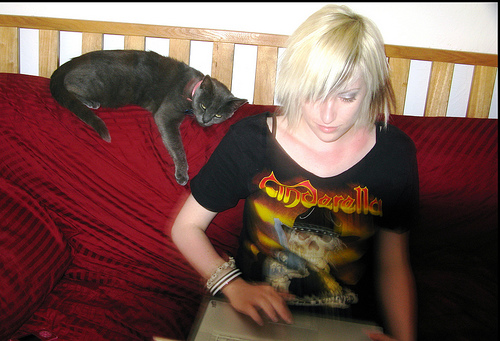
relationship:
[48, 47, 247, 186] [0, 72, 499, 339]
cat lazing on couch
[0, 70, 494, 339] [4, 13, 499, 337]
cushion on sofa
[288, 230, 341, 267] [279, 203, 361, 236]
skeleton wearing cowboy hat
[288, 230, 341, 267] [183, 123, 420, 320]
skeleton on shirt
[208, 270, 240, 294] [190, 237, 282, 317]
bracelet on wrist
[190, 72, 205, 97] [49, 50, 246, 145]
pink collar on cat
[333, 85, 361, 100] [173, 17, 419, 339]
eye shadow on girl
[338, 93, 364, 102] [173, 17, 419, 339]
mascara on girl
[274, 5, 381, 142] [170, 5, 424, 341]
head of girl